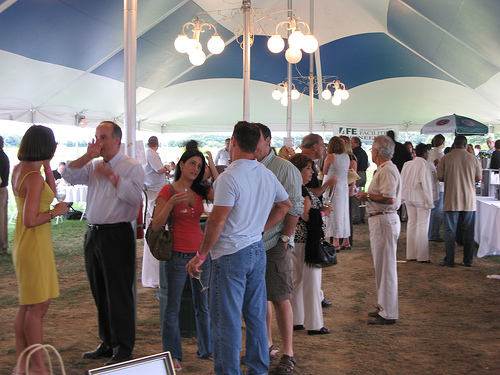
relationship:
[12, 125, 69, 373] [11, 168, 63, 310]
woman wearing yellow dress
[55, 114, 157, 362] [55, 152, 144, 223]
man wearing shirt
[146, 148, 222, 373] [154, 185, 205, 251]
woman wearing shirt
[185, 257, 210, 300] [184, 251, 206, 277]
glass in hand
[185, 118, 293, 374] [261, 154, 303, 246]
man wearing shirt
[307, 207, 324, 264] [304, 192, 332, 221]
scarf draped on arm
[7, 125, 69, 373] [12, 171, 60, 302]
woman wearing sundress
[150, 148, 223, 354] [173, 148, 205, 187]
woman scratching head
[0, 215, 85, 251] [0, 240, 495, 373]
grass on dirt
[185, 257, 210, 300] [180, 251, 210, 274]
glass in hand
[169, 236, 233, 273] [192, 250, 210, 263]
bracelet on wrist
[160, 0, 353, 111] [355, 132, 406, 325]
lights above person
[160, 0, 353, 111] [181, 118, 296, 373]
lights above person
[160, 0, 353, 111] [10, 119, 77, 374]
lights above person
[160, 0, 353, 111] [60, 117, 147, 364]
lights above person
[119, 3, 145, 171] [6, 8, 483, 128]
pole supporting tent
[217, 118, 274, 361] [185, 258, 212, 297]
man holding drink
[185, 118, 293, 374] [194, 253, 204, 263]
man wearing wristband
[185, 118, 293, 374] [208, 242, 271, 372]
man wearing jeans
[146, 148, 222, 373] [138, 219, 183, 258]
woman carrying purse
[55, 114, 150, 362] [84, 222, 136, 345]
man wearing pants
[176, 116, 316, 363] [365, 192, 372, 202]
man wearing watch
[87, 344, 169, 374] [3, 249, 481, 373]
frame sitting on ground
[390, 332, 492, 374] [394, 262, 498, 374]
dirt on ground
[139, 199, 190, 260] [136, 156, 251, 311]
purse hanging from shoulder of woman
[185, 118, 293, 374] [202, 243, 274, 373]
man wearing jeans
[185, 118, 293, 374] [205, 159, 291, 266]
man wearing shirt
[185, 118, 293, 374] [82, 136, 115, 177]
man talking with hands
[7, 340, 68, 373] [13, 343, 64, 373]
handles talking with bag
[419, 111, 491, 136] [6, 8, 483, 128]
umbrella under tent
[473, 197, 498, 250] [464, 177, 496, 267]
cloth on table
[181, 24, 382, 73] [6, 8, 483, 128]
chandelier hanging in tent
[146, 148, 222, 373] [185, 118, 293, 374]
woman having conversation with man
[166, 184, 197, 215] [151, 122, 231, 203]
finger combing through hair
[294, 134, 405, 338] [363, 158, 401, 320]
people are wearing formal wear